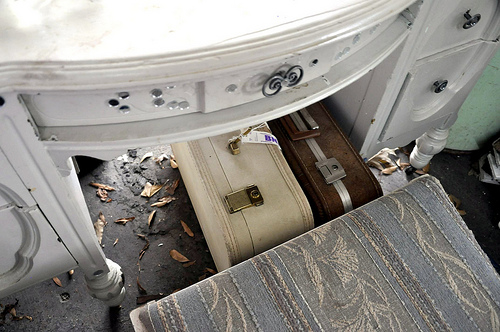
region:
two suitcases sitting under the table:
[173, 101, 383, 243]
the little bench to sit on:
[129, 178, 499, 330]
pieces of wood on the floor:
[93, 162, 208, 263]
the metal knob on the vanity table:
[265, 64, 300, 99]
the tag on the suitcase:
[238, 128, 287, 150]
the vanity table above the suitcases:
[2, 1, 497, 291]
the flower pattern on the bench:
[292, 230, 397, 329]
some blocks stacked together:
[474, 132, 499, 179]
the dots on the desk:
[100, 87, 193, 115]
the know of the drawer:
[458, 13, 479, 30]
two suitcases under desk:
[1, 0, 496, 302]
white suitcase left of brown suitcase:
[167, 102, 384, 274]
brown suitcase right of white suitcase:
[163, 99, 382, 270]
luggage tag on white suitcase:
[172, 119, 314, 271]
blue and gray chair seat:
[126, 174, 499, 330]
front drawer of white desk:
[15, 3, 408, 143]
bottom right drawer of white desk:
[379, 39, 494, 146]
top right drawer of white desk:
[415, 2, 499, 65]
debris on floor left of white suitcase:
[70, 119, 312, 318]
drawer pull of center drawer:
[258, 62, 304, 97]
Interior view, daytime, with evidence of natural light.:
[0, 1, 497, 331]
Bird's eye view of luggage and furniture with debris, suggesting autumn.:
[6, 7, 492, 331]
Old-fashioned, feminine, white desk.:
[4, 8, 488, 285]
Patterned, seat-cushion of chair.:
[132, 176, 499, 331]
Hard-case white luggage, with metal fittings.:
[184, 125, 309, 264]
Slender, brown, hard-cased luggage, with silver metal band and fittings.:
[292, 113, 370, 213]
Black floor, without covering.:
[100, 173, 194, 275]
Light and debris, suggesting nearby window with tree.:
[97, 155, 199, 279]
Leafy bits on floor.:
[88, 172, 196, 276]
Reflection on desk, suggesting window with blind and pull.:
[20, 5, 113, 44]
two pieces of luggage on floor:
[2, 12, 492, 327]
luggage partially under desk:
[137, 105, 397, 280]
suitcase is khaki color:
[146, 120, 312, 261]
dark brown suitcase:
[265, 80, 375, 222]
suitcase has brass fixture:
[216, 162, 271, 227]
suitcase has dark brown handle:
[281, 112, 326, 152]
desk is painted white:
[0, 3, 476, 295]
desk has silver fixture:
[222, 60, 327, 102]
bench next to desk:
[110, 164, 494, 328]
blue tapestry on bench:
[140, 120, 498, 329]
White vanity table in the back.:
[0, 0, 497, 302]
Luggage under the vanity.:
[159, 99, 384, 275]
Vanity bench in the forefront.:
[124, 175, 499, 330]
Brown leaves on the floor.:
[82, 153, 217, 284]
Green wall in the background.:
[440, 48, 497, 163]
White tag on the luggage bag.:
[234, 124, 285, 149]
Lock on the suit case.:
[224, 182, 266, 213]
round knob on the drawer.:
[428, 76, 451, 96]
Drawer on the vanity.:
[2, 3, 409, 149]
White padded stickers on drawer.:
[107, 83, 194, 118]